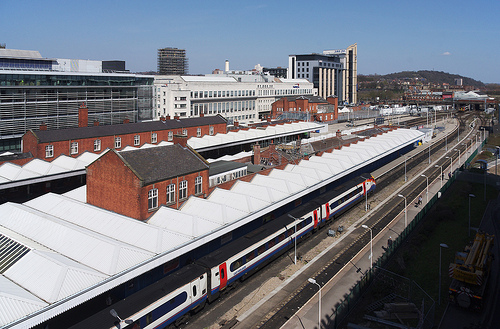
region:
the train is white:
[106, 160, 386, 327]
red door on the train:
[208, 249, 246, 297]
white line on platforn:
[228, 125, 460, 311]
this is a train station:
[0, 90, 427, 325]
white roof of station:
[28, 123, 422, 323]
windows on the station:
[129, 176, 213, 207]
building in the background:
[0, 30, 363, 130]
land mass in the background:
[353, 43, 493, 116]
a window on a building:
[140, 188, 163, 205]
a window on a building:
[162, 176, 175, 197]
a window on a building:
[175, 176, 181, 186]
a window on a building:
[190, 169, 204, 199]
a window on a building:
[44, 140, 56, 164]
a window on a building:
[67, 136, 82, 156]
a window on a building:
[94, 140, 104, 155]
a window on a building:
[114, 136, 126, 158]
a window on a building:
[130, 130, 142, 155]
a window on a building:
[141, 128, 169, 145]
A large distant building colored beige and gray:
[295, 42, 361, 98]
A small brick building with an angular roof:
[87, 136, 213, 213]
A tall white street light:
[302, 273, 326, 328]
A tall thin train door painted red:
[215, 258, 230, 292]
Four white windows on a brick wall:
[138, 172, 208, 209]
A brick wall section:
[92, 168, 118, 198]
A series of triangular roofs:
[187, 173, 303, 203]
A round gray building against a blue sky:
[157, 40, 190, 70]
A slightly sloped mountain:
[375, 53, 475, 86]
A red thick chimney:
[75, 103, 92, 125]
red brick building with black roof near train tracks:
[80, 125, 213, 227]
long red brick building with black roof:
[15, 100, 230, 165]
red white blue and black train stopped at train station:
[0, 167, 377, 327]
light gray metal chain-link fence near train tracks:
[337, 260, 439, 327]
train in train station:
[73, 169, 380, 327]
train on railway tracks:
[69, 173, 379, 328]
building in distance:
[1, 71, 161, 151]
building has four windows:
[82, 140, 208, 220]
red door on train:
[216, 260, 227, 286]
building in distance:
[289, 46, 358, 107]